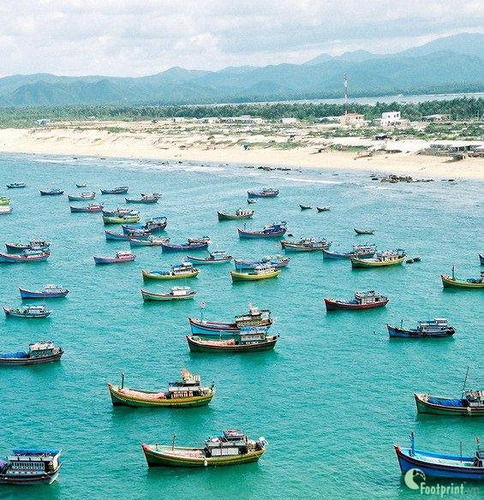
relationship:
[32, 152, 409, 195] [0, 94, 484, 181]
waves are on beach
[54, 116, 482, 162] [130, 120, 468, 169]
grass on beach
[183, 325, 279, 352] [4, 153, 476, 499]
fishing boat in ocean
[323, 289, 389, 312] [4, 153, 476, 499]
boat in ocean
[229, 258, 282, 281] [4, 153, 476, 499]
boat in ocean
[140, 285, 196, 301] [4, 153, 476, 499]
boat in ocean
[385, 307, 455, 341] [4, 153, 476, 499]
fishing boat in ocean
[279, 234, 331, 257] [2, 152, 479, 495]
boat in water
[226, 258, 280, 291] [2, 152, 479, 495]
boat in water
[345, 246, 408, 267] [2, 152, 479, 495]
boat in water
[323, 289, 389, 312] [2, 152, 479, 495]
boat in water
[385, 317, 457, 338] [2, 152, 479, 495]
boat in water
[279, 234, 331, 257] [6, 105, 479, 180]
boat near shore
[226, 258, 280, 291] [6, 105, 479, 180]
boat near shore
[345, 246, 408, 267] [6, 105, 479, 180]
boat near shore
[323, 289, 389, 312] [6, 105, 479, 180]
boat near shore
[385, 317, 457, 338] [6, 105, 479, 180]
boat near shore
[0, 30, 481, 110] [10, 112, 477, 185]
mountains are behind shore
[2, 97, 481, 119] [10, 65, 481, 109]
trees are on mountains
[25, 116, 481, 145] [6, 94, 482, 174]
seaweed on shore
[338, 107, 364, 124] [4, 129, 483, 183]
buildings are on beach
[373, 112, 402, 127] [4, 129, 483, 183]
buildings are on beach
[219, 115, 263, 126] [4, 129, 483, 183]
buildings are on beach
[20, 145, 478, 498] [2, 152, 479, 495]
ripples are in water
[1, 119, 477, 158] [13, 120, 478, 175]
sand/beach on beach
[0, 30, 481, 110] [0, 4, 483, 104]
mountains are in background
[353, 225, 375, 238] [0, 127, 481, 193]
small boats are by shore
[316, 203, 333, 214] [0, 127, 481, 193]
small boats are by shore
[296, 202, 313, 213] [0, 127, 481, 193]
small boats are by shore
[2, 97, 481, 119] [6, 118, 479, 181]
trees are behind beach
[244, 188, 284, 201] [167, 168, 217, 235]
boat in water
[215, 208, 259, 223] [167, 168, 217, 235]
boat in water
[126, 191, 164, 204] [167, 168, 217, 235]
boat in water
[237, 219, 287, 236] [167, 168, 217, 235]
boat in water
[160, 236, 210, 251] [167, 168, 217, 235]
boat in water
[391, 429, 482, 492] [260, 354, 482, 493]
blue boat in water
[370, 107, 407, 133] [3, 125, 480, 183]
buildings are on sand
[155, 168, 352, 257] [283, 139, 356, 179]
boats near sand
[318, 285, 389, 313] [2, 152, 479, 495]
boat on water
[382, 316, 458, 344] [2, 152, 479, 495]
boat on water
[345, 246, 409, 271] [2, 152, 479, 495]
boat on water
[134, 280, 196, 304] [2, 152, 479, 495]
boat on water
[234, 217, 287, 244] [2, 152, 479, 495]
boat on water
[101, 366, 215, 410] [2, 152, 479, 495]
boat on water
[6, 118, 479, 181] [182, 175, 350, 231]
beach against water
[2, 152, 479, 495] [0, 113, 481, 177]
water along beach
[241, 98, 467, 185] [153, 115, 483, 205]
buildings on beach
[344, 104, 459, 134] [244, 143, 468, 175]
buildings on beach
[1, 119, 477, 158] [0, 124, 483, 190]
sand/beach on beach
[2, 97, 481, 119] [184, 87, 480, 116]
trees on beach